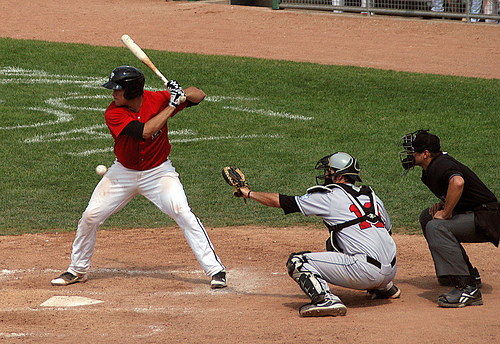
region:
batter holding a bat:
[46, 21, 236, 295]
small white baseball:
[91, 161, 108, 174]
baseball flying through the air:
[93, 163, 104, 175]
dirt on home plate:
[36, 285, 109, 310]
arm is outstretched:
[217, 160, 326, 230]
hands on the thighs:
[418, 196, 453, 226]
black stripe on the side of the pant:
[173, 167, 236, 266]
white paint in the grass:
[1, 57, 333, 163]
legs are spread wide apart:
[38, 185, 237, 296]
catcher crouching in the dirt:
[213, 128, 409, 325]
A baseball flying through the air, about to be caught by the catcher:
[95, 163, 109, 178]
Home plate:
[40, 295, 103, 308]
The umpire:
[400, 130, 497, 309]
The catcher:
[220, 150, 400, 312]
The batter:
[52, 34, 229, 290]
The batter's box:
[1, 268, 228, 337]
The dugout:
[229, 0, 497, 24]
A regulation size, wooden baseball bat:
[121, 35, 185, 102]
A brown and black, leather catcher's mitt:
[222, 165, 251, 202]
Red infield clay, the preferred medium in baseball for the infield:
[0, 233, 498, 341]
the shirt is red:
[99, 103, 179, 178]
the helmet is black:
[89, 63, 149, 106]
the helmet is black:
[101, 63, 168, 121]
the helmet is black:
[94, 65, 201, 139]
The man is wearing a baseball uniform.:
[49, 20, 235, 298]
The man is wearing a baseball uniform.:
[218, 136, 407, 331]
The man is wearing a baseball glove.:
[218, 137, 407, 321]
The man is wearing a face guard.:
[218, 140, 411, 323]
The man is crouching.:
[216, 146, 413, 324]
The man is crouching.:
[391, 115, 498, 320]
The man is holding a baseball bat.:
[42, 28, 229, 293]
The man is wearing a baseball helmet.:
[41, 22, 237, 292]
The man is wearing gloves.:
[42, 30, 236, 293]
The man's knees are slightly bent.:
[44, 30, 235, 291]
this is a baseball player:
[61, 47, 193, 282]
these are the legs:
[80, 180, 209, 284]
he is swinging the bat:
[64, 37, 211, 284]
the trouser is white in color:
[150, 173, 176, 205]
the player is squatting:
[278, 148, 391, 303]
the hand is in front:
[222, 162, 294, 214]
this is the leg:
[278, 245, 328, 301]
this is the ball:
[96, 164, 111, 175]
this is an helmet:
[317, 150, 355, 180]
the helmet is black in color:
[114, 65, 141, 85]